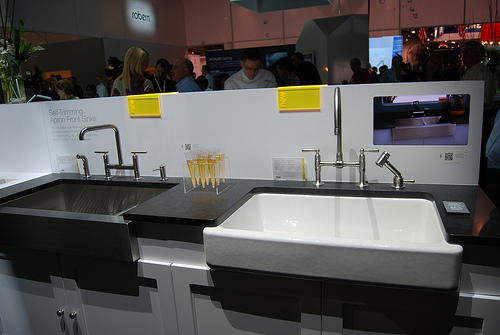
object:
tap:
[333, 86, 343, 160]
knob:
[300, 149, 319, 152]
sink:
[0, 178, 179, 263]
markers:
[127, 92, 178, 118]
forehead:
[243, 59, 260, 68]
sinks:
[203, 192, 464, 288]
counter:
[0, 172, 499, 244]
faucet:
[77, 123, 146, 179]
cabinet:
[320, 281, 500, 334]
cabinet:
[171, 264, 321, 334]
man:
[223, 49, 277, 89]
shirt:
[223, 69, 278, 90]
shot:
[207, 157, 217, 189]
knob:
[130, 151, 147, 154]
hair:
[116, 46, 151, 91]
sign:
[40, 97, 105, 174]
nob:
[54, 308, 62, 317]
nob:
[68, 311, 78, 322]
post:
[276, 84, 321, 111]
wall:
[0, 80, 485, 186]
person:
[348, 57, 372, 83]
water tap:
[68, 183, 145, 214]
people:
[109, 46, 155, 97]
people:
[146, 58, 176, 95]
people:
[458, 40, 493, 192]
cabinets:
[185, 0, 233, 46]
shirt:
[109, 75, 155, 96]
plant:
[0, 0, 50, 103]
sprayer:
[374, 150, 416, 188]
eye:
[244, 67, 252, 70]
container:
[183, 146, 231, 194]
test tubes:
[197, 154, 205, 188]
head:
[168, 57, 193, 81]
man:
[169, 57, 201, 92]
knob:
[358, 147, 380, 152]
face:
[242, 59, 259, 79]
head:
[125, 47, 150, 71]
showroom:
[0, 0, 499, 332]